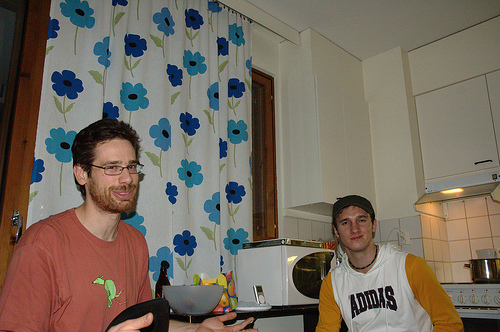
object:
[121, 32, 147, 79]
print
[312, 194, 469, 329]
man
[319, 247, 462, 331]
shirt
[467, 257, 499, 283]
pot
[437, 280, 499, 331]
stove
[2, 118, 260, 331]
man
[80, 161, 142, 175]
glasses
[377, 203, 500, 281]
backsplash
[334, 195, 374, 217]
hat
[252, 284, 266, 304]
music player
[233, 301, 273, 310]
docking station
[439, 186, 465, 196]
light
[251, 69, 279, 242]
window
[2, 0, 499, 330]
kitchen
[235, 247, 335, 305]
microwave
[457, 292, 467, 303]
dial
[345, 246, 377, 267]
necklace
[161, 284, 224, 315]
bowl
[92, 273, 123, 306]
dog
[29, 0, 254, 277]
curtain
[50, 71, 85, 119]
flower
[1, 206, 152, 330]
tee shirt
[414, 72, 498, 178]
cabinet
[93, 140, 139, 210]
face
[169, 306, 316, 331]
counter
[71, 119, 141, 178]
hair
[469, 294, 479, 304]
knob